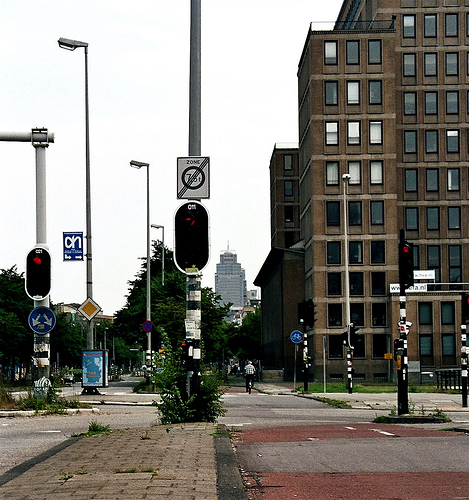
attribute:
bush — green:
[146, 328, 229, 428]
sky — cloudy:
[217, 30, 264, 239]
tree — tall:
[118, 244, 239, 371]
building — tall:
[213, 244, 245, 326]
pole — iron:
[185, 0, 202, 385]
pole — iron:
[29, 125, 50, 396]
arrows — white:
[30, 311, 52, 329]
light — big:
[52, 34, 89, 50]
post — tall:
[72, 54, 100, 296]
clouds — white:
[8, 10, 263, 297]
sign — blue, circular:
[28, 306, 54, 336]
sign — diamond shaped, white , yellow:
[78, 296, 102, 320]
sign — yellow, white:
[71, 291, 110, 324]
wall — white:
[214, 251, 244, 310]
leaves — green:
[5, 318, 19, 342]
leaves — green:
[6, 278, 26, 295]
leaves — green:
[125, 301, 135, 319]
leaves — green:
[159, 303, 183, 319]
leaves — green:
[213, 313, 221, 333]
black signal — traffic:
[398, 239, 415, 291]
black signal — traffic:
[300, 294, 314, 329]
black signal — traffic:
[171, 201, 211, 273]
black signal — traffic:
[25, 245, 51, 297]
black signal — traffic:
[461, 288, 468, 322]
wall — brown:
[273, 0, 465, 354]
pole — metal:
[179, 283, 218, 412]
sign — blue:
[290, 329, 302, 342]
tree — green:
[1, 263, 32, 379]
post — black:
[185, 275, 204, 421]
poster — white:
[181, 314, 196, 337]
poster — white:
[191, 347, 202, 360]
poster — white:
[185, 345, 193, 356]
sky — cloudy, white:
[2, 5, 343, 309]